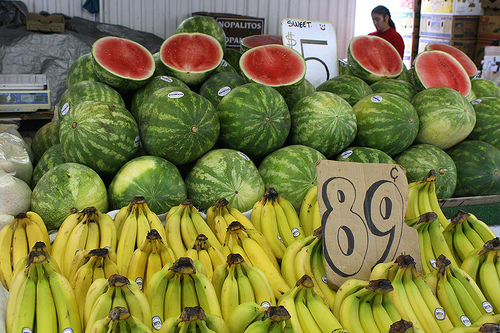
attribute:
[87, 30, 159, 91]
watermelon — sliced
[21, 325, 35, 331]
sticker — round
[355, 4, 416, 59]
man — wearing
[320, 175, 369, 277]
hand drawn — 8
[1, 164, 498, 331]
banana pile — large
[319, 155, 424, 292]
sign — brown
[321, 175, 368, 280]
number — 8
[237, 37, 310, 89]
fruit — pink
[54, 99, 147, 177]
water melon — half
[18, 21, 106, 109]
tarp — gray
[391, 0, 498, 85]
boxes — tall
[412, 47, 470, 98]
watermelon — cut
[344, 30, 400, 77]
watermelon — cut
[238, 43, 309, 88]
watermelon — cut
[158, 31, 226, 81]
watermelon — cut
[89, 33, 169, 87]
watermelon — cut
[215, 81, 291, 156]
watermelon — large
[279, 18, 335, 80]
sign — white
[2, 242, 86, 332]
banana bunch — green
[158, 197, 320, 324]
banana — yellow, ripe, a bunch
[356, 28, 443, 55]
shirt — red, tee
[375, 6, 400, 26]
hair — long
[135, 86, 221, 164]
watermelon — large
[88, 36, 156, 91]
watermelon — cut in half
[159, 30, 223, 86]
watermelon — cut in half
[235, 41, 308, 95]
watermelon — cut in half